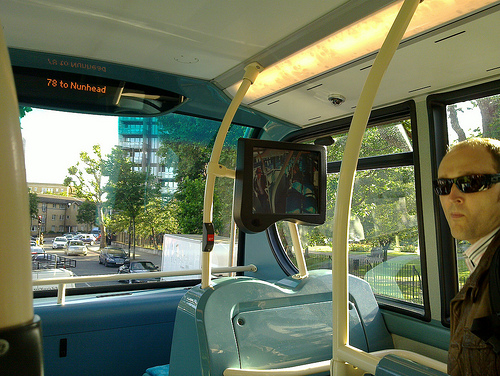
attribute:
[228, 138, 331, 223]
telivision — black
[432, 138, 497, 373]
man — bald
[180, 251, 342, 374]
seat — part, bus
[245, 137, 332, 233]
monitor — black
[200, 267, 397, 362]
seat — bus, aqua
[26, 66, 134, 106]
letters — orange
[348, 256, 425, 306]
fence — black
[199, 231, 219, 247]
button — red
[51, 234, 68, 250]
car — small, white